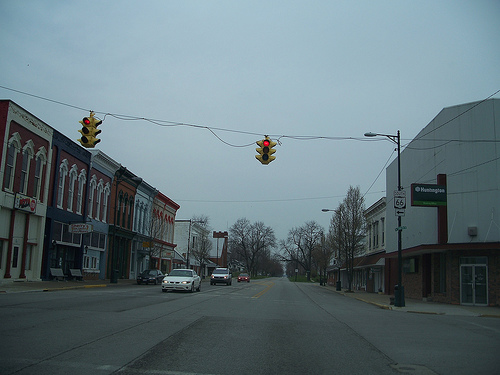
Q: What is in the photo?
A: Traffic.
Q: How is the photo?
A: Clear.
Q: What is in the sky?
A: Nothing.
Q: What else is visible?
A: Traffic lights.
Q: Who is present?
A: No one.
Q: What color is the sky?
A: Gray.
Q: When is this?
A: Evening.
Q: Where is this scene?
A: Town street.